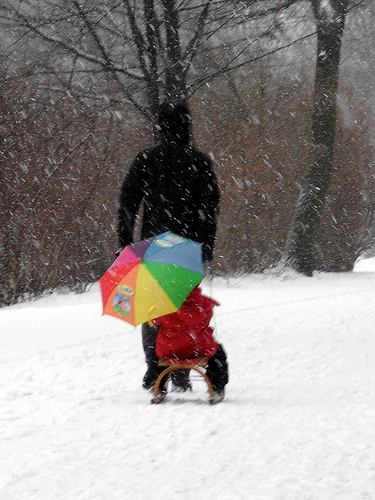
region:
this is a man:
[114, 90, 218, 241]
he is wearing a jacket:
[109, 103, 230, 229]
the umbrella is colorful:
[112, 235, 172, 294]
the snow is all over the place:
[257, 385, 362, 498]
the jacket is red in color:
[169, 312, 205, 363]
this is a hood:
[158, 102, 190, 145]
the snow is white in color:
[243, 381, 354, 498]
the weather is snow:
[245, 100, 357, 242]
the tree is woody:
[111, 5, 210, 86]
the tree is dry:
[116, 8, 221, 95]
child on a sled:
[80, 191, 278, 427]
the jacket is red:
[86, 241, 269, 421]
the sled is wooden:
[78, 197, 279, 463]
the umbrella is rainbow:
[84, 229, 223, 376]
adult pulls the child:
[75, 68, 263, 434]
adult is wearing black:
[99, 74, 264, 416]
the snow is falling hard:
[90, 26, 253, 191]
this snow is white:
[227, 437, 332, 480]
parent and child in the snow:
[90, 76, 263, 408]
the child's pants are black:
[130, 323, 256, 405]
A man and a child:
[74, 70, 242, 427]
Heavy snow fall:
[14, 21, 364, 261]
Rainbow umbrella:
[92, 232, 237, 329]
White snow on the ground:
[267, 260, 350, 427]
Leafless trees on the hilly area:
[14, 5, 345, 155]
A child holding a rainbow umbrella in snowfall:
[94, 222, 252, 397]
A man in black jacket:
[95, 82, 242, 286]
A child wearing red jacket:
[144, 280, 257, 410]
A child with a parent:
[96, 78, 264, 410]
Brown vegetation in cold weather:
[220, 78, 347, 255]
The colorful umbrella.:
[98, 231, 203, 327]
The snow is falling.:
[246, 102, 373, 240]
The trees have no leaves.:
[17, 2, 373, 77]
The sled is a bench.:
[149, 358, 221, 407]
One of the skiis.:
[148, 389, 169, 404]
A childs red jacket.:
[162, 296, 211, 356]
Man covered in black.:
[119, 96, 224, 237]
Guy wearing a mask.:
[164, 111, 185, 141]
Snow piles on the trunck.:
[268, 254, 311, 281]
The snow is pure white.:
[290, 338, 373, 468]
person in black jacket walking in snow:
[107, 80, 235, 420]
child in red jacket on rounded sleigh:
[142, 292, 240, 417]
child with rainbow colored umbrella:
[105, 220, 225, 359]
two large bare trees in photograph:
[88, 20, 347, 268]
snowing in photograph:
[25, 36, 347, 250]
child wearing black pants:
[131, 357, 240, 389]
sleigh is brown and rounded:
[130, 355, 237, 404]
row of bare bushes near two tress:
[9, 64, 365, 246]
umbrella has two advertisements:
[106, 211, 213, 324]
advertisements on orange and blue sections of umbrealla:
[75, 240, 233, 332]